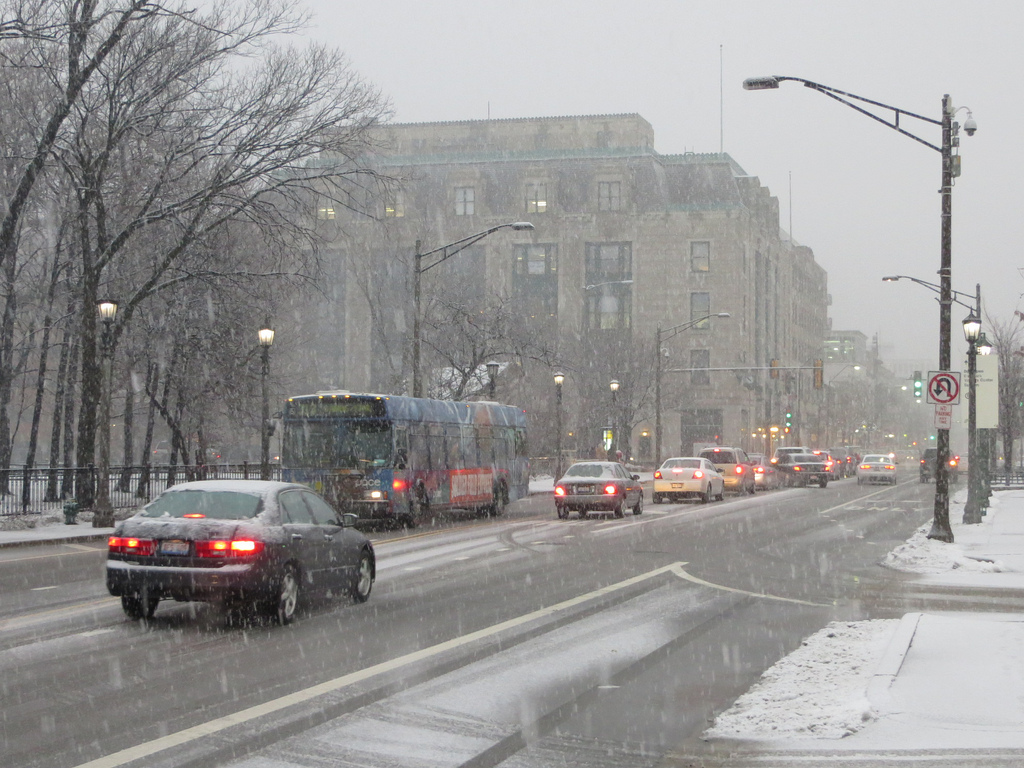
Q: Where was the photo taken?
A: It was taken at the street.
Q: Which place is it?
A: It is a street.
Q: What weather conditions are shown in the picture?
A: It is cloudy.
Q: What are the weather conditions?
A: It is cloudy.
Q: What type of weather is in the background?
A: It is cloudy.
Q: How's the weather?
A: It is cloudy.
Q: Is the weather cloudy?
A: Yes, it is cloudy.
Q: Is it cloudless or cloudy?
A: It is cloudy.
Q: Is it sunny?
A: No, it is cloudy.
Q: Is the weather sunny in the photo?
A: No, it is cloudy.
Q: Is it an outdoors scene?
A: Yes, it is outdoors.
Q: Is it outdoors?
A: Yes, it is outdoors.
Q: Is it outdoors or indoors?
A: It is outdoors.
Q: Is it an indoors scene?
A: No, it is outdoors.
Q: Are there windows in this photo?
A: Yes, there are windows.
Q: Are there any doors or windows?
A: Yes, there are windows.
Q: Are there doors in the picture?
A: No, there are no doors.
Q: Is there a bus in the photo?
A: Yes, there is a bus.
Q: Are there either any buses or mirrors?
A: Yes, there is a bus.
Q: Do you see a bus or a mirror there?
A: Yes, there is a bus.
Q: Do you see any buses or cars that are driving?
A: Yes, the bus is driving.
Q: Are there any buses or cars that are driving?
A: Yes, the bus is driving.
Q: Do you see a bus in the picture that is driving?
A: Yes, there is a bus that is driving.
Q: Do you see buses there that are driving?
A: Yes, there is a bus that is driving.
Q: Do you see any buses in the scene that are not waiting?
A: Yes, there is a bus that is driving .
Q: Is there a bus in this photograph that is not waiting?
A: Yes, there is a bus that is driving.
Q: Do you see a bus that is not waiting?
A: Yes, there is a bus that is driving .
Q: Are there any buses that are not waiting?
A: Yes, there is a bus that is driving.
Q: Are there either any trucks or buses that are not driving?
A: No, there is a bus but it is driving.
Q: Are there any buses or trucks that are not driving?
A: No, there is a bus but it is driving.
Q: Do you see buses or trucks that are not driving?
A: No, there is a bus but it is driving.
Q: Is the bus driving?
A: Yes, the bus is driving.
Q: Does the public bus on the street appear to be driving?
A: Yes, the bus is driving.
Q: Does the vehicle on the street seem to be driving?
A: Yes, the bus is driving.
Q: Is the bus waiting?
A: No, the bus is driving.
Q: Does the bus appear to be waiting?
A: No, the bus is driving.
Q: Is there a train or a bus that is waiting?
A: No, there is a bus but it is driving.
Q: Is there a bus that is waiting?
A: No, there is a bus but it is driving.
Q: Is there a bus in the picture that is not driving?
A: No, there is a bus but it is driving.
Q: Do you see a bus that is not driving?
A: No, there is a bus but it is driving.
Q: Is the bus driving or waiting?
A: The bus is driving.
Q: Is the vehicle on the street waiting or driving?
A: The bus is driving.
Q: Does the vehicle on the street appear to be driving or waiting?
A: The bus is driving.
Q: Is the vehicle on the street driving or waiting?
A: The bus is driving.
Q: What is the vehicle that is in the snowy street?
A: The vehicle is a bus.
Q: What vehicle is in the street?
A: The vehicle is a bus.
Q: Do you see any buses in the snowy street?
A: Yes, there is a bus in the street.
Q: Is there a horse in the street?
A: No, there is a bus in the street.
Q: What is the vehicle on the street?
A: The vehicle is a bus.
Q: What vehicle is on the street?
A: The vehicle is a bus.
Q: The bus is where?
A: The bus is on the street.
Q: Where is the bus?
A: The bus is on the street.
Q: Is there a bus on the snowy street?
A: Yes, there is a bus on the street.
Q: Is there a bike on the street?
A: No, there is a bus on the street.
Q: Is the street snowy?
A: Yes, the street is snowy.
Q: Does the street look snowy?
A: Yes, the street is snowy.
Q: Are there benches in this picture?
A: No, there are no benches.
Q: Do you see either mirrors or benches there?
A: No, there are no benches or mirrors.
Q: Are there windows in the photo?
A: Yes, there are windows.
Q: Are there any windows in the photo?
A: Yes, there are windows.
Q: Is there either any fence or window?
A: Yes, there are windows.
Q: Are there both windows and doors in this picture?
A: No, there are windows but no doors.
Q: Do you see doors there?
A: No, there are no doors.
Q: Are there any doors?
A: No, there are no doors.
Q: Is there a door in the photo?
A: No, there are no doors.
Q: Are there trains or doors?
A: No, there are no doors or trains.